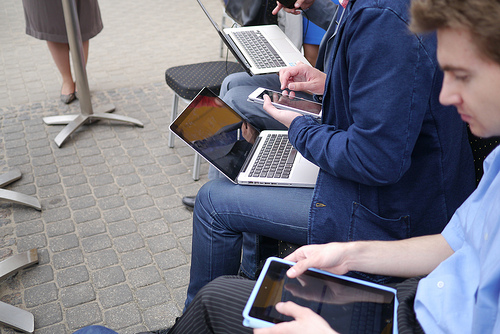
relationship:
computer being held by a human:
[170, 85, 321, 188] [179, 0, 498, 330]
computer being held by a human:
[170, 87, 320, 188] [186, 7, 476, 310]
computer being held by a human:
[177, 0, 318, 81] [181, 0, 338, 208]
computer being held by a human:
[248, 82, 323, 117] [186, 7, 476, 310]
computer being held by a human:
[248, 82, 323, 118] [179, 0, 480, 303]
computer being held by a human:
[170, 85, 321, 188] [179, 0, 480, 303]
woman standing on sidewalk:
[23, 0, 103, 105] [1, 0, 224, 332]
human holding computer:
[179, 0, 480, 303] [248, 82, 323, 118]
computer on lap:
[170, 87, 320, 188] [210, 176, 318, 243]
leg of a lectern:
[44, 114, 80, 124] [46, 0, 142, 146]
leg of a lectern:
[95, 106, 117, 112] [46, 0, 142, 146]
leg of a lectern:
[93, 114, 144, 126] [46, 0, 142, 146]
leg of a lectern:
[54, 118, 85, 146] [46, 0, 142, 146]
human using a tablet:
[179, 0, 480, 303] [250, 89, 324, 120]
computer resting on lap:
[170, 87, 320, 188] [203, 184, 314, 240]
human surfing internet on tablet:
[179, 0, 480, 303] [218, 246, 439, 332]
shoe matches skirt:
[71, 83, 80, 103] [22, 0, 103, 44]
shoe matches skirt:
[60, 83, 73, 103] [22, 0, 103, 44]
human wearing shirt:
[179, 0, 480, 303] [406, 143, 498, 330]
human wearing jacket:
[179, 0, 480, 303] [286, 4, 479, 242]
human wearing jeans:
[179, 0, 480, 303] [130, 161, 315, 298]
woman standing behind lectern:
[23, 0, 103, 105] [40, 0, 145, 149]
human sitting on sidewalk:
[179, 0, 480, 303] [1, 0, 225, 334]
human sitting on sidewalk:
[181, 0, 342, 208] [1, 0, 225, 334]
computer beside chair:
[197, 0, 312, 74] [164, 0, 267, 180]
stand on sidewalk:
[30, 0, 144, 153] [1, 0, 225, 334]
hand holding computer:
[271, 59, 329, 99] [248, 82, 323, 118]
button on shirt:
[431, 277, 445, 291] [406, 143, 498, 330]